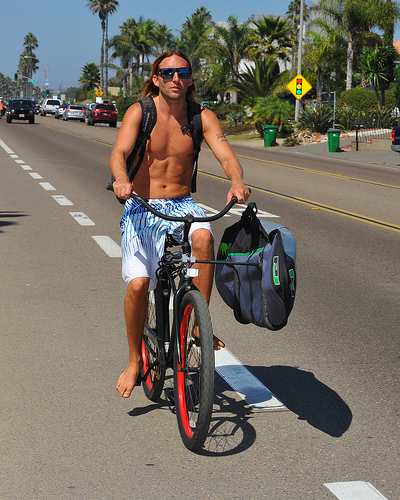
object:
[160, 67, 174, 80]
eye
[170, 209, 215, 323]
leg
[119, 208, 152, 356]
leg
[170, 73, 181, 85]
nose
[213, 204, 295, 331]
bag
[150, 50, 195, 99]
head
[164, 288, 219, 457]
tire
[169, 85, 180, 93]
mouth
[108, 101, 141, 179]
arm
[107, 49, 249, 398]
guy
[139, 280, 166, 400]
rear tire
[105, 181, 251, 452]
bike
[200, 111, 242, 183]
arm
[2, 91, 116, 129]
vehicles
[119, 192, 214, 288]
shorts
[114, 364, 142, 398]
feet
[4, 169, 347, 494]
lane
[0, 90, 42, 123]
traffic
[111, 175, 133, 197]
hand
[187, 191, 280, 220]
lettering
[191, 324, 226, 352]
foot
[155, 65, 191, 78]
sunglasses